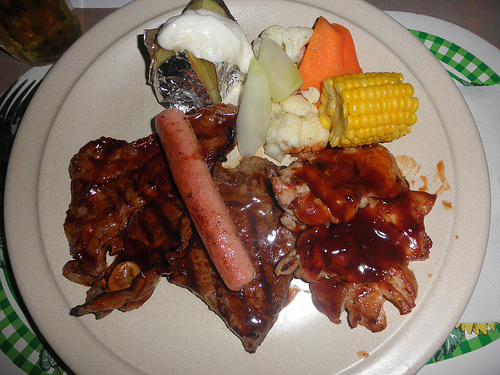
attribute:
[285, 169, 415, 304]
meat — barbecued pulled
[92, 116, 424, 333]
meat — bgrilled barbecued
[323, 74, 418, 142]
cob — small 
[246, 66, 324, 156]
potato — tiny baked 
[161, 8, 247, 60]
cream — sour  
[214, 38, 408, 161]
vegetables — bunch , different 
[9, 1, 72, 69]
drink — wash 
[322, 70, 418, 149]
maize — yellow  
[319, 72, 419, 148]
corn — mini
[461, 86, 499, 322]
napkin — white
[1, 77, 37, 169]
fork — metallic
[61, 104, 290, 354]
steak — grilled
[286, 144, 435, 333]
chicken — grilled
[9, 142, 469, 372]
plate — white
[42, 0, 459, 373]
plate — white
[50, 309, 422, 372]
plate — white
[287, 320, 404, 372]
plate — white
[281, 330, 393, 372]
plate — white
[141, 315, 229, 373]
plate — white